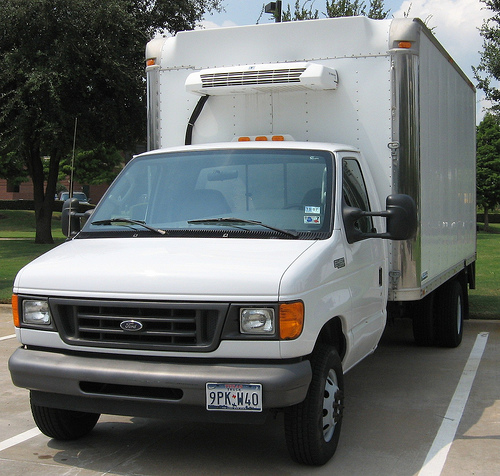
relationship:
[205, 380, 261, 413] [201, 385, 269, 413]
this is a license plate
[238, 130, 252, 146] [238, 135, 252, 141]
this is a small orange this is a small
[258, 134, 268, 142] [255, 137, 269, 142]
this is a small orange light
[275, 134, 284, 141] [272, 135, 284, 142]
this is a small orange this is headlight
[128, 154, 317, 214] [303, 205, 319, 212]
windshield have a these sticker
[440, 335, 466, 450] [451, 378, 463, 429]
stripe on road is white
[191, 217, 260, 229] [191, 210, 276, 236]
this is a black windshield wiper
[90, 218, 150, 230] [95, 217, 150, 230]
this is a a black wiper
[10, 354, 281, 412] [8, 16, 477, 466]
this is a bumper this truck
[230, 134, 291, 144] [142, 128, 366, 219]
this is headlight on front of vehicle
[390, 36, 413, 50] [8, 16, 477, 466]
this is headlight on front this truck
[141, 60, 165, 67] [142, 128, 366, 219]
this is headlight on front of vehicle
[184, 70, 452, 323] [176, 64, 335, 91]
this truck have a vent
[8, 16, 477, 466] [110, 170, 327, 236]
this truck have windshield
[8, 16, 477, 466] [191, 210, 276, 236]
this truck have wiper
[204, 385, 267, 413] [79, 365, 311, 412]
lincense in front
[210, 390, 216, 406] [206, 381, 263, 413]
this is a 9 number on plate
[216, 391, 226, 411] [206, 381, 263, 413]
this a p on plate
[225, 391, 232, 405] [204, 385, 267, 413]
this is a k on license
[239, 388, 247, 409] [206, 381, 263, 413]
this is a w on plate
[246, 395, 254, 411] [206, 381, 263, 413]
this is a  4 on plate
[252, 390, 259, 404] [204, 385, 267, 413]
this is a 0 on license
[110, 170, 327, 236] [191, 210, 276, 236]
these windshield has wiper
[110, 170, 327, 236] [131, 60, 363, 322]
these is front windshield on the truck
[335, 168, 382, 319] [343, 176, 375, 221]
this the door of driver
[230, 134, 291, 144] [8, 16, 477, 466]
this is headlight on this truck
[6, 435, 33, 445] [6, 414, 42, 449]
this stripe on cement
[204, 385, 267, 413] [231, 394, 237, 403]
this license from texas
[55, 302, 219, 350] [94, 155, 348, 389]
this grill front wehicle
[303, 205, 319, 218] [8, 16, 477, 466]
these sticker on this truck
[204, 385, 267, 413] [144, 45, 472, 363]
license on truck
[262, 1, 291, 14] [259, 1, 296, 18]
light on street in the top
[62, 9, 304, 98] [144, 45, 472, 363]
top tree behind truck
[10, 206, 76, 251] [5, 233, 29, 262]
these is landscpae in the grass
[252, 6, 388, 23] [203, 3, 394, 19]
this is blue cloudy sky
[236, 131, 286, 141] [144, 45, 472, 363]
headlight on truck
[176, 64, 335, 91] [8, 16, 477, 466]
vent for this truck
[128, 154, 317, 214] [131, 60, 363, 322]
windshield have wiper on the truck